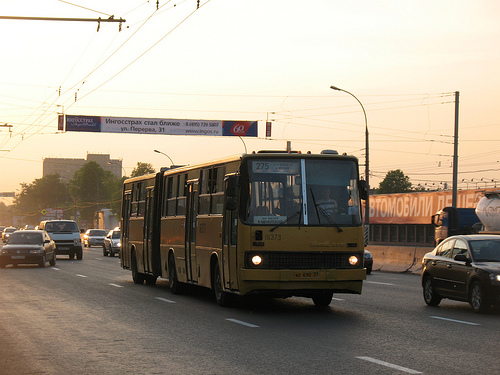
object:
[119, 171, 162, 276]
cabin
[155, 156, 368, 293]
cabin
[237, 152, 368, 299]
front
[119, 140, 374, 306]
bus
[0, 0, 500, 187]
sky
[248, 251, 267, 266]
headlights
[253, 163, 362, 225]
windshield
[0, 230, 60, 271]
cars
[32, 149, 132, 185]
building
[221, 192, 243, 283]
door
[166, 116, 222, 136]
sign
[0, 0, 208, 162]
cables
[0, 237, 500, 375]
road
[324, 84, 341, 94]
light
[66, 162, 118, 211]
trees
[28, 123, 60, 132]
sunlight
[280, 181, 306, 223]
driver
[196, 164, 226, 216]
window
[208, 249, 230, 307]
tires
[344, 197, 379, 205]
lettering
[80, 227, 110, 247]
van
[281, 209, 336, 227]
blades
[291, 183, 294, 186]
number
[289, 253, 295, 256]
grill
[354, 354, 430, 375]
lines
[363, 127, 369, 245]
pole